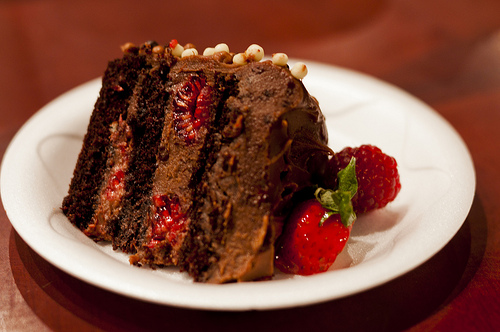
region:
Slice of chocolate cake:
[71, 50, 321, 217]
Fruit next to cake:
[240, 133, 409, 235]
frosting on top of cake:
[185, 65, 324, 239]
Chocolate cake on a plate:
[76, 79, 339, 274]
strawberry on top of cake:
[283, 198, 348, 273]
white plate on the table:
[333, 57, 490, 180]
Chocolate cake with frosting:
[47, 58, 220, 235]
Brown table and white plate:
[8, 206, 121, 301]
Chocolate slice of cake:
[67, 49, 367, 244]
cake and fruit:
[196, 116, 402, 263]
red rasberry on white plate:
[332, 138, 403, 216]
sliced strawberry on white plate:
[272, 158, 365, 275]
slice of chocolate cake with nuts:
[58, 29, 344, 289]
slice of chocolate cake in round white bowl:
[2, 33, 484, 315]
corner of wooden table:
[1, 208, 46, 325]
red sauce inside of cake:
[144, 189, 188, 261]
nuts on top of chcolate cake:
[177, 37, 312, 88]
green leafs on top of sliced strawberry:
[314, 153, 359, 234]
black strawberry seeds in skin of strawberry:
[295, 238, 328, 269]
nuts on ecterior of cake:
[125, 38, 307, 76]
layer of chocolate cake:
[60, 53, 142, 226]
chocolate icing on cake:
[223, 66, 330, 281]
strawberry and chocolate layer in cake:
[140, 57, 225, 264]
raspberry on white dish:
[333, 145, 398, 213]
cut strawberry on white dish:
[278, 203, 355, 270]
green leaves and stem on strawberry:
[312, 155, 357, 225]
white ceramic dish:
[0, 51, 475, 306]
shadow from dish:
[5, 196, 480, 326]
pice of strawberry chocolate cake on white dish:
[63, 41, 333, 281]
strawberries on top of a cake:
[283, 152, 347, 264]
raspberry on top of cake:
[309, 135, 417, 200]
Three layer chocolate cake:
[80, 53, 307, 222]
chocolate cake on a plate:
[61, 38, 371, 253]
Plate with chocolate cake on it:
[30, 38, 485, 328]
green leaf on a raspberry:
[311, 175, 358, 210]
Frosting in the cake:
[63, 74, 233, 238]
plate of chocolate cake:
[63, 45, 372, 267]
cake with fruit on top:
[224, 61, 444, 288]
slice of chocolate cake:
[43, 80, 173, 221]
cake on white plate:
[2, 34, 475, 308]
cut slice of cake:
[66, 40, 323, 280]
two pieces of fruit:
[278, 143, 399, 275]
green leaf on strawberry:
[278, 155, 367, 275]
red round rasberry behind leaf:
[334, 143, 401, 213]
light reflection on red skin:
[283, 200, 348, 265]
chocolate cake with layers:
[72, 46, 286, 273]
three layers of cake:
[70, 55, 231, 268]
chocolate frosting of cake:
[217, 58, 325, 273]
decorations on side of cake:
[129, 35, 309, 79]